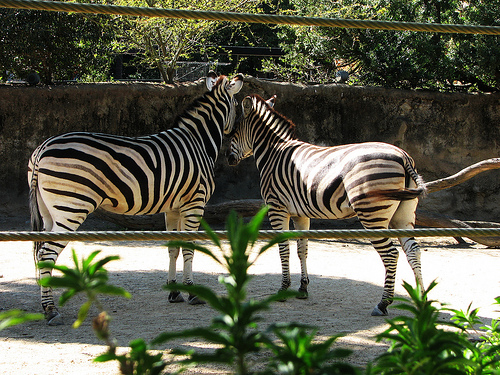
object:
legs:
[267, 213, 290, 301]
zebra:
[224, 94, 429, 316]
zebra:
[28, 73, 243, 326]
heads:
[224, 94, 275, 166]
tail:
[28, 161, 43, 252]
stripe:
[66, 134, 190, 212]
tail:
[369, 155, 426, 211]